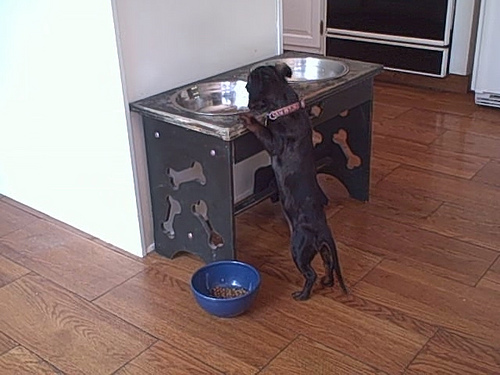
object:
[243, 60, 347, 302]
dog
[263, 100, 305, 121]
collar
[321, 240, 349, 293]
tail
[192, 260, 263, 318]
bowl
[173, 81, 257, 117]
bowl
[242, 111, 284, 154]
arm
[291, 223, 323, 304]
leg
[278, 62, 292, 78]
ear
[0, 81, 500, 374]
floor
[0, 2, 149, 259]
wall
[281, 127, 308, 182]
fur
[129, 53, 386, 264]
feeder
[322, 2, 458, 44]
appliance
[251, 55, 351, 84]
sink